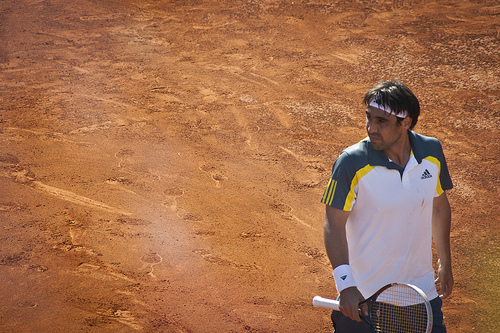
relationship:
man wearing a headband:
[319, 81, 454, 331] [365, 93, 407, 118]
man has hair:
[319, 81, 454, 331] [363, 80, 420, 131]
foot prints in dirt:
[3, 143, 294, 331] [3, 5, 498, 330]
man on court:
[319, 81, 454, 331] [1, 0, 497, 330]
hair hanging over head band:
[359, 89, 444, 151] [361, 90, 409, 115]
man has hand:
[319, 81, 454, 331] [334, 282, 369, 324]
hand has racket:
[334, 282, 369, 324] [310, 282, 434, 332]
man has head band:
[319, 81, 454, 331] [361, 90, 409, 115]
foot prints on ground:
[200, 247, 258, 272] [1, 0, 498, 330]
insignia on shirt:
[418, 166, 434, 180] [317, 128, 452, 307]